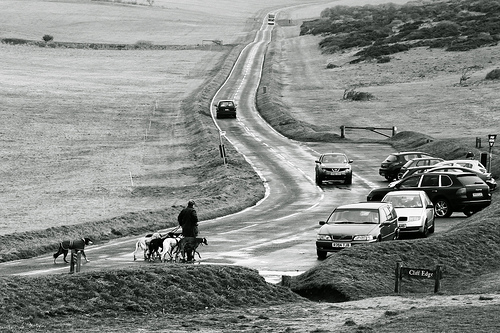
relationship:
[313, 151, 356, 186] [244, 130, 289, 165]
car on road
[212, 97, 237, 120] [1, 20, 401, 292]
car on road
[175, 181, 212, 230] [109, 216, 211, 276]
man with dogs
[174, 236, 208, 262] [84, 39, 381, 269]
dog on road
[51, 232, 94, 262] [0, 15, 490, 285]
dog on road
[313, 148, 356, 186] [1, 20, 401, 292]
car on road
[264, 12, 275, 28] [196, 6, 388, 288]
bus on road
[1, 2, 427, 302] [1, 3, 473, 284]
road with road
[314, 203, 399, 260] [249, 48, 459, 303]
car parked on roadside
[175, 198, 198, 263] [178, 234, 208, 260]
man with dog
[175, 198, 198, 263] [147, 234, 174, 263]
man with dog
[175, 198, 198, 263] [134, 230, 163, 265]
man with dog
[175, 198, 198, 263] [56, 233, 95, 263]
man with dog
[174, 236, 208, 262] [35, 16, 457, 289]
dog on road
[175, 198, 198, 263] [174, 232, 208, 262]
man walking dog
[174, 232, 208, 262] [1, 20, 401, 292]
dog on road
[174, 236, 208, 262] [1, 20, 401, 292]
dog on road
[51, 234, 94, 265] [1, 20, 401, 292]
dog on road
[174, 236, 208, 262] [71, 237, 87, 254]
dog in vest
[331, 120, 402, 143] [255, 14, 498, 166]
gate between hills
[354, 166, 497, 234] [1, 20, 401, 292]
car facing road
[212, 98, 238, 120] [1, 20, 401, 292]
car driving on road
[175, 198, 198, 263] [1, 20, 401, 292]
man on road